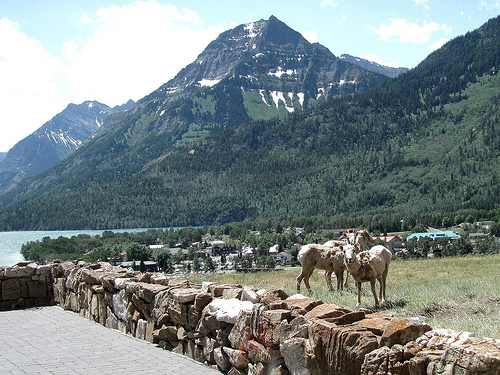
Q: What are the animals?
A: Sheep.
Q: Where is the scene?
A: On a farm.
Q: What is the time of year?
A: Spring.